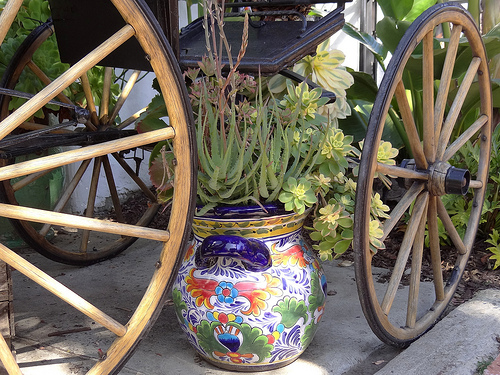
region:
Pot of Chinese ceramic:
[163, 196, 333, 370]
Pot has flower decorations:
[162, 201, 331, 371]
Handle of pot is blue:
[190, 227, 274, 272]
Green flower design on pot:
[266, 293, 311, 331]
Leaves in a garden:
[326, 0, 498, 237]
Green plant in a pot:
[127, 14, 381, 205]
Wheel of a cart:
[2, 0, 210, 374]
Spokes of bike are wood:
[2, 4, 156, 350]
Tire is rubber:
[350, 20, 390, 339]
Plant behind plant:
[11, 0, 123, 172]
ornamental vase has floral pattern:
[162, 170, 331, 372]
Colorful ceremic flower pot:
[174, 197, 319, 373]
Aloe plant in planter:
[173, 84, 327, 208]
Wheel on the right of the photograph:
[354, 2, 496, 338]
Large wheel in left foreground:
[0, 2, 205, 373]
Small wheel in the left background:
[4, 17, 182, 262]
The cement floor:
[4, 209, 486, 373]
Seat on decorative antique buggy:
[64, 5, 367, 76]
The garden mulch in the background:
[116, 164, 498, 279]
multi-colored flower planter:
[167, 194, 317, 374]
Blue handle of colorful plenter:
[196, 231, 267, 273]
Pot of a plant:
[160, 196, 334, 373]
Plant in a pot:
[142, 31, 387, 211]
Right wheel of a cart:
[340, 1, 497, 349]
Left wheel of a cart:
[3, 11, 179, 270]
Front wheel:
[4, 1, 199, 370]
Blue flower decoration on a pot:
[209, 269, 245, 309]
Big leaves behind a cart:
[354, 0, 495, 165]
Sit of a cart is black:
[171, 8, 345, 88]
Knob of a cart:
[434, 154, 482, 209]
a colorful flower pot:
[178, 206, 328, 371]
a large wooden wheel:
[350, 0, 492, 348]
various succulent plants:
[169, 1, 386, 261]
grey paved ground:
[86, 271, 131, 293]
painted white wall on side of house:
[131, 92, 143, 102]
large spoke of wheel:
[390, 150, 470, 195]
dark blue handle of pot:
[193, 235, 269, 271]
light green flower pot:
[0, 135, 65, 246]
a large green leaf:
[308, 7, 388, 62]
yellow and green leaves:
[301, 36, 355, 91]